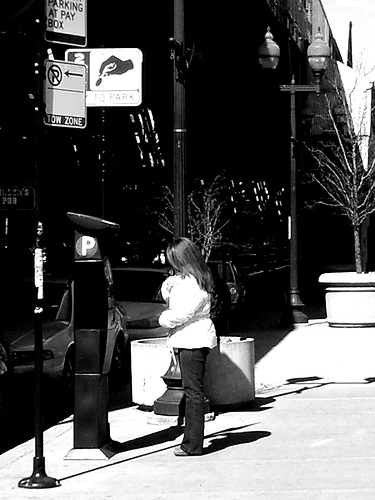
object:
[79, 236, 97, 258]
writing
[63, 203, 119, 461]
machine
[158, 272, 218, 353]
coat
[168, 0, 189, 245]
pole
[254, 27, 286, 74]
lights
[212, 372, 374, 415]
shadow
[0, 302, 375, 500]
ground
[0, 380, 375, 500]
road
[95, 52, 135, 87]
design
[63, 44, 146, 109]
sign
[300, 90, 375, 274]
tree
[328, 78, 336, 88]
leaves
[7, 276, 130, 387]
car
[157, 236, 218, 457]
woman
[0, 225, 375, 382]
street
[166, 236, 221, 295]
hair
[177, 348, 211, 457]
pants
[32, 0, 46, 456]
pole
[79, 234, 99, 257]
p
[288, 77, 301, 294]
pole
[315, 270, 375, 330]
pot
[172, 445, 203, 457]
shoes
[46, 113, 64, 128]
towing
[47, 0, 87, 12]
parking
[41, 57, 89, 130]
sign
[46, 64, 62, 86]
no parking